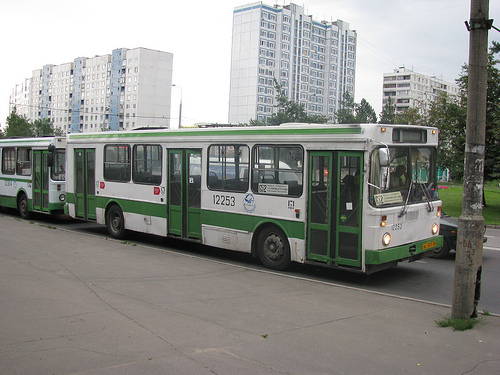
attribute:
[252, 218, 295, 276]
tire — side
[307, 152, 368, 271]
doors — green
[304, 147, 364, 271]
door — green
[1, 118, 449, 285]
buses — parked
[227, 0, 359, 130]
building — multilevel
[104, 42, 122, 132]
stripes — blue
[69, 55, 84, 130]
stripes — blue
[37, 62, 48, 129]
stripes — blue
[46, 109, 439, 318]
bus — city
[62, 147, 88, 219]
door — back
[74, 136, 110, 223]
door — back